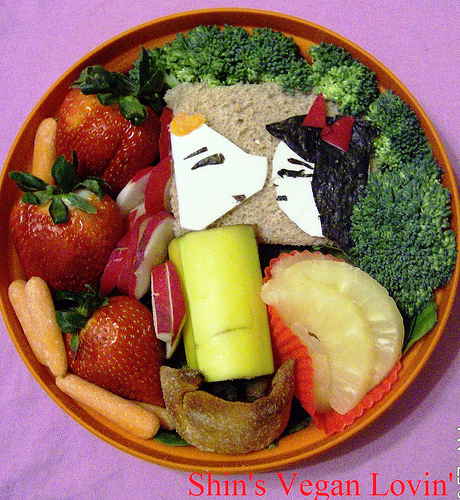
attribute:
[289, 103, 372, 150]
bow — red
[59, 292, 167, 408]
strawberry — red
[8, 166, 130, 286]
strawberry — red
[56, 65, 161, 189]
strawberry — red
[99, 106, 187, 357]
salad — tossed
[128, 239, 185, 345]
apple — sliced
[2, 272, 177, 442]
carrots — cut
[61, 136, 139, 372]
strawberry — red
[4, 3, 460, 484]
round plate — orange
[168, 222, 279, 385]
pineapple — yellow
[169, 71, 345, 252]
bread — brown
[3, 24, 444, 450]
salad — tossed